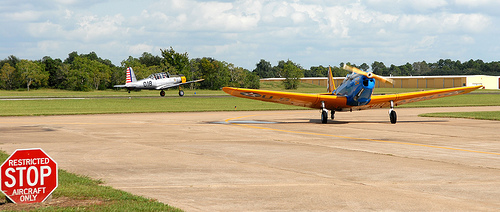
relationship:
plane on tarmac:
[219, 63, 486, 124] [60, 120, 483, 204]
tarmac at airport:
[60, 120, 483, 204] [1, 55, 484, 206]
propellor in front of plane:
[338, 61, 396, 91] [219, 63, 486, 124]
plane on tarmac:
[219, 63, 486, 124] [1, 102, 496, 209]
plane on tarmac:
[113, 57, 207, 101] [1, 102, 496, 209]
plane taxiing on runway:
[219, 63, 486, 124] [0, 105, 497, 210]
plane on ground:
[219, 63, 486, 124] [0, 89, 499, 210]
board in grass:
[3, 148, 60, 205] [57, 166, 181, 210]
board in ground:
[3, 148, 60, 205] [36, 77, 489, 207]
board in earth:
[3, 127, 93, 205] [0, 149, 178, 209]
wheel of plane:
[390, 109, 395, 124] [219, 63, 486, 124]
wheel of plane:
[319, 109, 329, 124] [219, 63, 486, 124]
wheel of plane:
[329, 113, 335, 120] [219, 63, 486, 124]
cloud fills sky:
[368, 9, 488, 38] [0, 1, 499, 70]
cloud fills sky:
[22, 21, 125, 44] [0, 1, 499, 70]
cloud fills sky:
[165, 7, 257, 34] [0, 1, 499, 70]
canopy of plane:
[152, 73, 169, 80] [111, 65, 205, 97]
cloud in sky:
[368, 9, 488, 38] [0, 1, 499, 70]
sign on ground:
[2, 146, 59, 203] [0, 149, 183, 209]